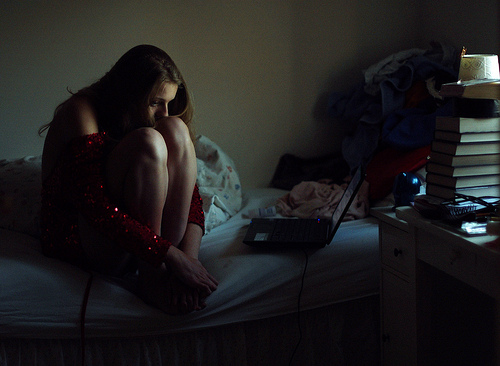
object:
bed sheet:
[0, 186, 382, 340]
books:
[421, 159, 498, 179]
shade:
[311, 89, 357, 158]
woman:
[39, 44, 221, 317]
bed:
[2, 180, 379, 364]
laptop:
[240, 162, 368, 253]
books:
[429, 112, 499, 136]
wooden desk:
[368, 202, 499, 364]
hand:
[161, 246, 221, 298]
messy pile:
[264, 37, 462, 223]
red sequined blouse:
[36, 130, 207, 272]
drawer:
[378, 227, 414, 280]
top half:
[455, 51, 500, 80]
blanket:
[0, 132, 244, 244]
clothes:
[276, 172, 369, 223]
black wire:
[286, 245, 313, 365]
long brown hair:
[34, 43, 198, 147]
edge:
[0, 216, 379, 336]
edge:
[395, 207, 500, 263]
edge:
[242, 239, 327, 252]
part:
[143, 127, 168, 161]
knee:
[121, 126, 170, 165]